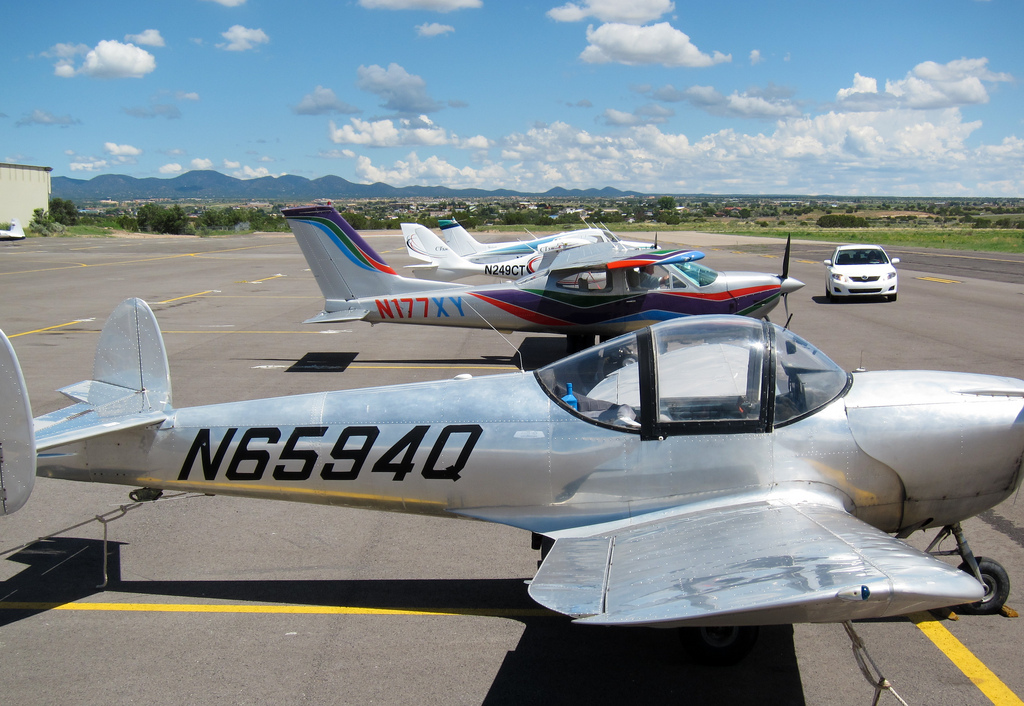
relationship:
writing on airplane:
[173, 410, 491, 506] [11, 285, 996, 666]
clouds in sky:
[289, 60, 969, 215] [205, 16, 927, 187]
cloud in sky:
[60, 17, 166, 85] [205, 16, 927, 187]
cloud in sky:
[579, 22, 711, 69] [205, 16, 927, 187]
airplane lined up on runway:
[11, 313, 1008, 633] [103, 250, 294, 471]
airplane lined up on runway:
[267, 198, 810, 380] [103, 250, 294, 471]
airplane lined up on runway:
[402, 196, 658, 285] [103, 250, 294, 471]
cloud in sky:
[618, 60, 708, 130] [99, 8, 815, 212]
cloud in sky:
[702, 66, 791, 121] [58, 23, 866, 242]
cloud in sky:
[842, 65, 897, 114] [52, 14, 947, 213]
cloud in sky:
[298, 89, 357, 115] [38, 17, 976, 268]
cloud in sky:
[209, 21, 255, 53] [34, 14, 992, 231]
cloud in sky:
[63, 27, 159, 79] [173, 137, 254, 190]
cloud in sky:
[137, 28, 173, 52] [26, 102, 582, 247]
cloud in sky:
[566, 2, 759, 94] [61, 115, 977, 139]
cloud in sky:
[405, 24, 456, 41] [15, 102, 204, 280]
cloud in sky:
[298, 89, 357, 115] [110, 137, 290, 254]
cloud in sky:
[298, 89, 357, 115] [58, 139, 182, 192]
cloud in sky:
[298, 95, 363, 124] [132, 104, 889, 156]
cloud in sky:
[218, 21, 255, 52] [52, 139, 1022, 224]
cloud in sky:
[129, 29, 168, 49] [153, 102, 603, 200]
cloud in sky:
[48, 37, 81, 79] [108, 107, 724, 157]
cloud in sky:
[45, 29, 80, 53] [84, 167, 1018, 219]